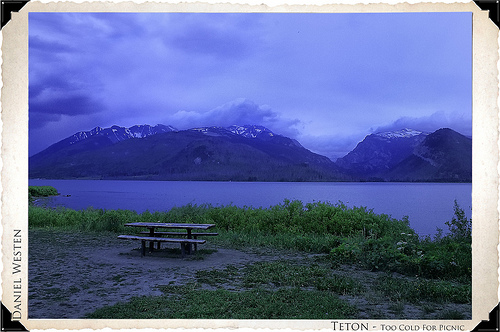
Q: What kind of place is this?
A: It is a shore.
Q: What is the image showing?
A: It is showing a shore.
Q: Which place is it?
A: It is a shore.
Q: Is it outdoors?
A: Yes, it is outdoors.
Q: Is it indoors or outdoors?
A: It is outdoors.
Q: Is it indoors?
A: No, it is outdoors.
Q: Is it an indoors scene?
A: No, it is outdoors.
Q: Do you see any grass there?
A: Yes, there is grass.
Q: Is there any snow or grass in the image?
A: Yes, there is grass.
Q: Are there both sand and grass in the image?
A: No, there is grass but no sand.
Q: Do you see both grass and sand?
A: No, there is grass but no sand.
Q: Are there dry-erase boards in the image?
A: No, there are no dry-erase boards.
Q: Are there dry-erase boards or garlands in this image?
A: No, there are no dry-erase boards or garlands.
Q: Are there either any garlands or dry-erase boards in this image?
A: No, there are no dry-erase boards or garlands.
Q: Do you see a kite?
A: No, there are no kites.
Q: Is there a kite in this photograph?
A: No, there are no kites.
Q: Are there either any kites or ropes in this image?
A: No, there are no kites or ropes.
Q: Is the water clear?
A: Yes, the water is clear.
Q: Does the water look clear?
A: Yes, the water is clear.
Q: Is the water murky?
A: No, the water is clear.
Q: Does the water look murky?
A: No, the water is clear.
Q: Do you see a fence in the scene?
A: No, there are no fences.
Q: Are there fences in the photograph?
A: No, there are no fences.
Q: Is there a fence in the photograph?
A: No, there are no fences.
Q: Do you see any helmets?
A: No, there are no helmets.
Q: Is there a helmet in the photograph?
A: No, there are no helmets.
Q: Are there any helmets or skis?
A: No, there are no helmets or skis.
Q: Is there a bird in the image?
A: No, there are no birds.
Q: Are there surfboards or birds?
A: No, there are no birds or surfboards.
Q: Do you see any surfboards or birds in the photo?
A: No, there are no birds or surfboards.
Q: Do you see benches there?
A: Yes, there is a bench.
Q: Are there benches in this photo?
A: Yes, there is a bench.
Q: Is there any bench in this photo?
A: Yes, there is a bench.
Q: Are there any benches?
A: Yes, there is a bench.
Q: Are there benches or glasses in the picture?
A: Yes, there is a bench.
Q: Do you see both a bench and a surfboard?
A: No, there is a bench but no surfboards.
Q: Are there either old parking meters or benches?
A: Yes, there is an old bench.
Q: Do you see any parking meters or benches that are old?
A: Yes, the bench is old.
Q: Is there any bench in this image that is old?
A: Yes, there is an old bench.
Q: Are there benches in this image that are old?
A: Yes, there is a bench that is old.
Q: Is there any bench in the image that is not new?
A: Yes, there is a old bench.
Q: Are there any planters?
A: No, there are no planters.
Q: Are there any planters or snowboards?
A: No, there are no planters or snowboards.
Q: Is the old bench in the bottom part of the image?
A: Yes, the bench is in the bottom of the image.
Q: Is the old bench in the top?
A: No, the bench is in the bottom of the image.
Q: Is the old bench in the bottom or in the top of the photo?
A: The bench is in the bottom of the image.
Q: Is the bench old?
A: Yes, the bench is old.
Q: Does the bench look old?
A: Yes, the bench is old.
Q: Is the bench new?
A: No, the bench is old.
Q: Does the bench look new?
A: No, the bench is old.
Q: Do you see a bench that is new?
A: No, there is a bench but it is old.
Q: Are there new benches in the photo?
A: No, there is a bench but it is old.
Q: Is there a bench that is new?
A: No, there is a bench but it is old.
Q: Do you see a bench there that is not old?
A: No, there is a bench but it is old.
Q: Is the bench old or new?
A: The bench is old.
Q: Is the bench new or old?
A: The bench is old.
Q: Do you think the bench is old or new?
A: The bench is old.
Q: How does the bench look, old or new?
A: The bench is old.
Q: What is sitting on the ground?
A: The bench is sitting on the ground.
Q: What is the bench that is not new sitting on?
A: The bench is sitting on the ground.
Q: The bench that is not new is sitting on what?
A: The bench is sitting on the ground.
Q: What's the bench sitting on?
A: The bench is sitting on the ground.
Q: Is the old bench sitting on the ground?
A: Yes, the bench is sitting on the ground.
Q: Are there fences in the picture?
A: No, there are no fences.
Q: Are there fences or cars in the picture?
A: No, there are no fences or cars.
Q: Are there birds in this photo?
A: No, there are no birds.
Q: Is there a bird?
A: No, there are no birds.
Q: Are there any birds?
A: No, there are no birds.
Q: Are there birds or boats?
A: No, there are no birds or boats.